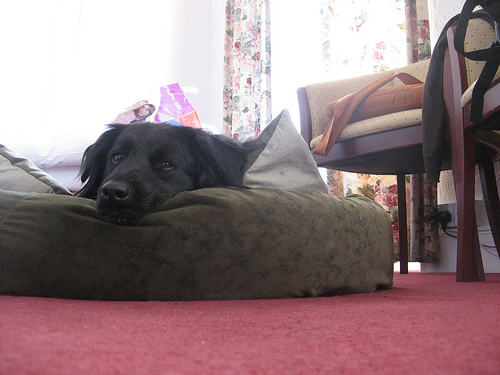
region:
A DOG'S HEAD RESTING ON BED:
[76, 115, 266, 226]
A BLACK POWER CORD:
[432, 205, 499, 257]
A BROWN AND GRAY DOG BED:
[0, 100, 417, 324]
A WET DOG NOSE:
[95, 176, 135, 206]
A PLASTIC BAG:
[96, 77, 221, 145]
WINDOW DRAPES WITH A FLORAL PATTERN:
[212, 0, 448, 277]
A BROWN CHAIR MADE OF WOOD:
[294, 2, 499, 294]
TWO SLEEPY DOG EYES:
[102, 145, 184, 176]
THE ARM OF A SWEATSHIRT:
[412, 5, 497, 197]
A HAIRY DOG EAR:
[184, 120, 266, 196]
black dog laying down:
[81, 104, 248, 242]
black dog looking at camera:
[78, 96, 286, 256]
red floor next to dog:
[183, 298, 315, 368]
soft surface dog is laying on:
[226, 196, 308, 262]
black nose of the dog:
[97, 171, 144, 216]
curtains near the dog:
[219, 62, 295, 104]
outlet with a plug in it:
[424, 203, 464, 240]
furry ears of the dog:
[193, 118, 248, 198]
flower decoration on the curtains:
[223, 61, 270, 130]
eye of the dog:
[151, 143, 184, 188]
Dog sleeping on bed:
[71, 104, 253, 228]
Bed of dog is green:
[4, 183, 404, 304]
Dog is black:
[60, 109, 254, 239]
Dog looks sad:
[59, 106, 256, 246]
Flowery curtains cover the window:
[205, 0, 450, 276]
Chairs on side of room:
[291, 1, 498, 286]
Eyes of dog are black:
[97, 143, 178, 174]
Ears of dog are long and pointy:
[59, 120, 256, 187]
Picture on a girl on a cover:
[105, 79, 210, 130]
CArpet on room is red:
[9, 265, 499, 371]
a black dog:
[63, 96, 272, 240]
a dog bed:
[4, 144, 406, 319]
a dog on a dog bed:
[55, 101, 420, 317]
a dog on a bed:
[9, 112, 405, 309]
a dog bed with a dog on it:
[15, 109, 412, 314]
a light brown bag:
[317, 52, 443, 158]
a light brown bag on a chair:
[266, 13, 498, 262]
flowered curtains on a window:
[213, 3, 483, 270]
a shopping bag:
[82, 74, 282, 162]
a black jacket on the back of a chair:
[413, 0, 488, 290]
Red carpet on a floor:
[31, 291, 324, 374]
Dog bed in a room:
[13, 177, 398, 289]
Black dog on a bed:
[75, 119, 271, 208]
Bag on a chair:
[320, 67, 450, 127]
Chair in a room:
[302, 54, 497, 211]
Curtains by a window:
[211, 5, 306, 205]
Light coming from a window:
[273, 11, 374, 131]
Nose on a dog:
[91, 174, 146, 214]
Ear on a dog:
[184, 128, 223, 167]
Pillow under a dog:
[228, 116, 330, 178]